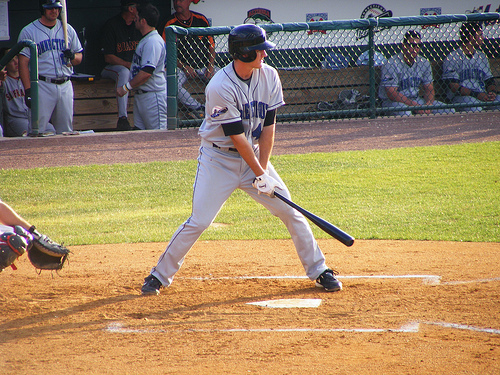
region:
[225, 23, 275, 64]
black helmet on the batter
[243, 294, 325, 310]
white home plate in the dirt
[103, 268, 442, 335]
white lines for the batter's boxes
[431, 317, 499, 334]
white line on the field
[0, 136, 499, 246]
green grass on the field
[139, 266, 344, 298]
black cleats on the player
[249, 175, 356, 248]
black bat in the batter's hands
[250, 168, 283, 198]
white batting gloves on the batter's hands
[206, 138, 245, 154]
black belt in the gray pants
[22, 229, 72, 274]
black and brown glove on the catcher's hand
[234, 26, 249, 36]
man wearing blue helmet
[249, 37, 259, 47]
black stripe around helmet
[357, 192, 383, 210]
green grass in field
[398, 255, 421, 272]
brown dirt in field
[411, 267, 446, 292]
white line in dirt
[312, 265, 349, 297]
man wearing blue sneakers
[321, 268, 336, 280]
blue strings in sneakers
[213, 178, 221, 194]
man wearing white pants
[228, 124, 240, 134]
man wearing black shirt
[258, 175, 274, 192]
man wearing white gloves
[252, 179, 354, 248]
A black bat in a man's hand.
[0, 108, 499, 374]
A baseball field.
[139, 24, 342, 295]
A baseball player in uniform.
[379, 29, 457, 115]
A baseball player sitting in a dug out.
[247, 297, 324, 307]
A white baseball base.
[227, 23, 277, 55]
A dark blue baseball cap on a man's head.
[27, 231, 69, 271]
A leather baseball glove.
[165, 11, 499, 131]
A green fence in the distance.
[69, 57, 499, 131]
A wooden bench in dug out.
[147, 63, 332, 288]
A baseball uniform.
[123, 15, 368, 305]
player holding a bat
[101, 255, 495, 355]
white lines on the dirt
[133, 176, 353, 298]
legs are spread wide apart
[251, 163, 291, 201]
both hands on the bat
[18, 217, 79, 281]
brown and black baseball glove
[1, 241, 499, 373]
dirt on the ground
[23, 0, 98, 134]
player standing in the dugout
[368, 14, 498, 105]
players sitting in the dugout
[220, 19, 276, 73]
helmet on the head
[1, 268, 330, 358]
shadows on the dirt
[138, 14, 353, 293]
Baseball player holding a bat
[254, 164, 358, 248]
White batting gloves and black bat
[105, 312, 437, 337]
White lines in orange sand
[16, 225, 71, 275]
Tan baseball glove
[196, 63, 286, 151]
Gray uniform with blue letters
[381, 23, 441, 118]
Baseball player sitting on bench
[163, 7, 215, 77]
Player wearing orange and black shirt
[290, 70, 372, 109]
Back of wooden bench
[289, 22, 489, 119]
Green chain link fence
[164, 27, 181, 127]
Green fence post